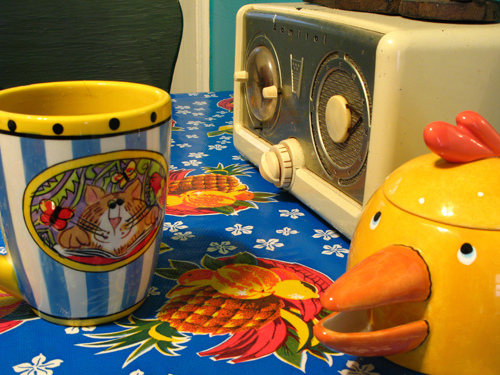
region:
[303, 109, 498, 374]
yellow chicken cookie jar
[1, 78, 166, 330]
colorful cat coffee mug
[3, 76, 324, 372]
table cloth with fruit designs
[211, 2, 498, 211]
white and metal toaster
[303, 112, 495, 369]
bird shaped cookie jar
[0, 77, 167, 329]
blue and white striped coffee mug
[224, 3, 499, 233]
toaster on a table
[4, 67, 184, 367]
mug on a table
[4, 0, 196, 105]
back of a black chair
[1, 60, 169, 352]
mug with a cat design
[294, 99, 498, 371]
bowl on the table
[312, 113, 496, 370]
bowl shaped like a chicken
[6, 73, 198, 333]
cup on the table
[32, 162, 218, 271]
cat on the cup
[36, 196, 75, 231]
butterfly beside the cat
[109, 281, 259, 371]
pineapple on the tablecloth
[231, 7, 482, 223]
large timer on the table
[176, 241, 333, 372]
fruit basket on the table cloth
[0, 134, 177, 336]
blue stripes on the cup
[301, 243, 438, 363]
beak on the bowl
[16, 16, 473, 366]
this is a kitchen area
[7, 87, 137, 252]
this is a coffee mug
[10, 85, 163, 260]
the coffee mug is painted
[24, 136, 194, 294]
the mug has a cat on it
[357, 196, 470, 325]
this is a chicken head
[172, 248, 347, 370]
this is a table cloth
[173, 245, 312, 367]
the table cloth has fruit on it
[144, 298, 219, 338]
this is a pineapple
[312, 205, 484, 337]
the chicken head is yellow and orange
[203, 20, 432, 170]
this is an appliance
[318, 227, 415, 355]
orange nose on cookie jar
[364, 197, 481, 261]
eyes looking upwards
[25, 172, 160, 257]
cartoon on the cup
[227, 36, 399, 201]
old fashion radio on the table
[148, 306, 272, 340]
orange and yellow acorn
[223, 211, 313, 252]
small white flowers on the table cloth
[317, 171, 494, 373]
cookie jar is yellow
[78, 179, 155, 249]
cat on front of cup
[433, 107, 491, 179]
orange feather on top of jar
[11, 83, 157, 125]
yellow rim on the cup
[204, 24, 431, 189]
An old radio on the table.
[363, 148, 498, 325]
A cookie jar made like a duck.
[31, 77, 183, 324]
Mug on the table.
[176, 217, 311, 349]
The tablecloth has fruits on it.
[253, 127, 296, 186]
White knob on the radio.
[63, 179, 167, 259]
A dog on the mug.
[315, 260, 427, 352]
Beak of the cookie jar.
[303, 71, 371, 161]
Dialer on the radio.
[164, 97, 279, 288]
The tablecloth has white leaves.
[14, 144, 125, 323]
The mug has blue and white strips.